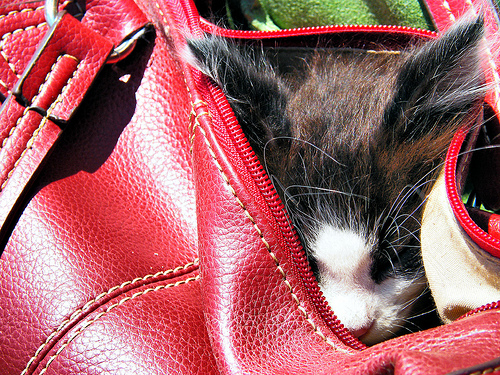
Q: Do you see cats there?
A: Yes, there is a cat.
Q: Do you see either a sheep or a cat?
A: Yes, there is a cat.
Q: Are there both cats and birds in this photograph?
A: No, there is a cat but no birds.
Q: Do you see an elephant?
A: No, there are no elephants.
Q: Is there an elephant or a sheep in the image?
A: No, there are no elephants or sheep.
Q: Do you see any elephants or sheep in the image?
A: No, there are no elephants or sheep.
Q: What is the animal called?
A: The animal is a cat.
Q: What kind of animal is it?
A: The animal is a cat.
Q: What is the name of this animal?
A: This is a cat.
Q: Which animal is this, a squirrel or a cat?
A: This is a cat.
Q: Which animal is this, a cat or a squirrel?
A: This is a cat.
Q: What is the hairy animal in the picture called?
A: The animal is a cat.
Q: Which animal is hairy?
A: The animal is a cat.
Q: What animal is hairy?
A: The animal is a cat.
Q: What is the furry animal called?
A: The animal is a cat.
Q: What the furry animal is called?
A: The animal is a cat.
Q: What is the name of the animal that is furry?
A: The animal is a cat.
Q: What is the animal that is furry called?
A: The animal is a cat.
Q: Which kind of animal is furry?
A: The animal is a cat.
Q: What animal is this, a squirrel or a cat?
A: This is a cat.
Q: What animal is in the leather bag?
A: The cat is in the bag.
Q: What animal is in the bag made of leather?
A: The cat is in the bag.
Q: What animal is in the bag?
A: The cat is in the bag.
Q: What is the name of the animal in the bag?
A: The animal is a cat.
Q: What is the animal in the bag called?
A: The animal is a cat.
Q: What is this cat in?
A: The cat is in the bag.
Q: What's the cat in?
A: The cat is in the bag.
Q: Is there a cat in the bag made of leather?
A: Yes, there is a cat in the bag.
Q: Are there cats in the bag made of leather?
A: Yes, there is a cat in the bag.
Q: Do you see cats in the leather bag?
A: Yes, there is a cat in the bag.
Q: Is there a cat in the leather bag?
A: Yes, there is a cat in the bag.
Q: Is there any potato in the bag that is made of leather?
A: No, there is a cat in the bag.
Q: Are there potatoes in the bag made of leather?
A: No, there is a cat in the bag.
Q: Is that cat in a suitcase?
A: No, the cat is in a bag.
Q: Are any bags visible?
A: Yes, there is a bag.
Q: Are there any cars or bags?
A: Yes, there is a bag.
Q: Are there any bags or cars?
A: Yes, there is a bag.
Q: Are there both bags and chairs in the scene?
A: No, there is a bag but no chairs.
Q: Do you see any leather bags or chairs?
A: Yes, there is a leather bag.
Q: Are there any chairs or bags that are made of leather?
A: Yes, the bag is made of leather.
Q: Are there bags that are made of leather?
A: Yes, there is a bag that is made of leather.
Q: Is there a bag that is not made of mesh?
A: Yes, there is a bag that is made of leather.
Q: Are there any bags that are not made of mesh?
A: Yes, there is a bag that is made of leather.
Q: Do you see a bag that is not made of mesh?
A: Yes, there is a bag that is made of leather.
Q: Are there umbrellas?
A: No, there are no umbrellas.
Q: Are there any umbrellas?
A: No, there are no umbrellas.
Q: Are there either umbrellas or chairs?
A: No, there are no umbrellas or chairs.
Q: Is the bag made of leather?
A: Yes, the bag is made of leather.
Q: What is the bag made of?
A: The bag is made of leather.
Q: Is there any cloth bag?
A: No, there is a bag but it is made of leather.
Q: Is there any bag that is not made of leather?
A: No, there is a bag but it is made of leather.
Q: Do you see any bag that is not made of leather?
A: No, there is a bag but it is made of leather.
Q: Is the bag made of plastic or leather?
A: The bag is made of leather.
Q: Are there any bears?
A: No, there are no bears.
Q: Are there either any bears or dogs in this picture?
A: No, there are no bears or dogs.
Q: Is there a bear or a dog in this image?
A: No, there are no bears or dogs.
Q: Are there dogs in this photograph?
A: No, there are no dogs.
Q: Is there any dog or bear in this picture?
A: No, there are no dogs or bears.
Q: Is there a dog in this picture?
A: No, there are no dogs.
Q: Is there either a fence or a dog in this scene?
A: No, there are no dogs or fences.